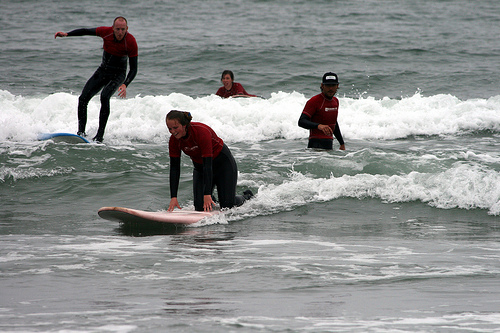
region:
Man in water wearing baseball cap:
[312, 70, 349, 153]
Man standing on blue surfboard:
[56, 10, 137, 157]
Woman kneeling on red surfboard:
[155, 101, 257, 228]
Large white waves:
[361, 94, 472, 144]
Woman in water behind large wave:
[207, 61, 264, 111]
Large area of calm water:
[162, 11, 474, 63]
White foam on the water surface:
[78, 238, 185, 261]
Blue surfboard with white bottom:
[32, 126, 92, 149]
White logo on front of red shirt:
[321, 105, 341, 114]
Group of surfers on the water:
[34, 13, 271, 259]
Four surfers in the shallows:
[46, 10, 358, 241]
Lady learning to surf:
[96, 106, 266, 235]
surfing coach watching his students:
[292, 67, 354, 161]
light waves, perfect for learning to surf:
[1, 86, 499, 232]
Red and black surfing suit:
[55, 24, 142, 148]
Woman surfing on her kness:
[96, 107, 263, 234]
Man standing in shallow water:
[291, 72, 364, 164]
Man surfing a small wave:
[30, 9, 147, 155]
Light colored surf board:
[92, 198, 237, 245]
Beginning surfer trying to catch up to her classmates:
[206, 66, 273, 111]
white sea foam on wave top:
[355, 92, 442, 132]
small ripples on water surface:
[270, 10, 470, 62]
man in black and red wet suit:
[27, 11, 154, 132]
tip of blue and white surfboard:
[32, 124, 89, 149]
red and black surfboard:
[87, 187, 209, 239]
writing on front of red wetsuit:
[177, 137, 203, 154]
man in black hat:
[291, 57, 365, 160]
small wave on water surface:
[32, 150, 157, 198]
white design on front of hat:
[322, 71, 337, 83]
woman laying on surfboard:
[204, 53, 282, 111]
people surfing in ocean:
[38, 15, 345, 228]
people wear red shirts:
[52, 16, 347, 212]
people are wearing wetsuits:
[52, 15, 347, 211]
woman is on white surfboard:
[92, 203, 249, 226]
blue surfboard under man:
[40, 131, 105, 151]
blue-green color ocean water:
[1, 1, 499, 330]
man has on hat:
[319, 71, 339, 86]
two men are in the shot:
[55, 14, 350, 213]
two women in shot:
[162, 66, 261, 210]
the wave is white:
[1, 91, 497, 138]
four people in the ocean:
[53, 2, 375, 235]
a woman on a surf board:
[91, 110, 243, 242]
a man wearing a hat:
[314, 66, 350, 108]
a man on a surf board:
[53, 7, 140, 160]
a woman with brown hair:
[216, 56, 263, 107]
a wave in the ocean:
[346, 75, 486, 165]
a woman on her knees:
[117, 107, 244, 227]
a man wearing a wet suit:
[73, 5, 135, 148]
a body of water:
[155, 2, 472, 79]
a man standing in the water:
[297, 55, 367, 168]